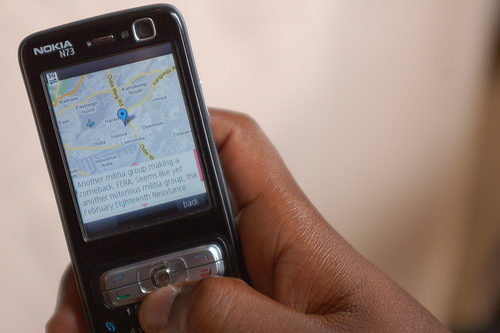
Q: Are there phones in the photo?
A: Yes, there is a phone.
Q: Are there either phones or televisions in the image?
A: Yes, there is a phone.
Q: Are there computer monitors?
A: No, there are no computer monitors.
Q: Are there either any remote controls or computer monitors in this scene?
A: No, there are no computer monitors or remote controls.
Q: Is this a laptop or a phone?
A: This is a phone.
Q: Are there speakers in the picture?
A: Yes, there is a speaker.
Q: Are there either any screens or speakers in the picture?
A: Yes, there is a speaker.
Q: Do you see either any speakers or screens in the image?
A: Yes, there is a speaker.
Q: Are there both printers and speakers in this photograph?
A: No, there is a speaker but no printers.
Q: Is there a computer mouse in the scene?
A: No, there are no computer mice.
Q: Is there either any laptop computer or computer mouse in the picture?
A: No, there are no computer mice or laptops.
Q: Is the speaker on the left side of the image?
A: Yes, the speaker is on the left of the image.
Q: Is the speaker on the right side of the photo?
A: No, the speaker is on the left of the image.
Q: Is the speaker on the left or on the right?
A: The speaker is on the left of the image.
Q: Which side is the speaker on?
A: The speaker is on the left of the image.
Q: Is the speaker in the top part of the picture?
A: Yes, the speaker is in the top of the image.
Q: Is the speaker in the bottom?
A: No, the speaker is in the top of the image.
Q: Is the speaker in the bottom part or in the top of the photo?
A: The speaker is in the top of the image.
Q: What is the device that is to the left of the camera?
A: The device is a speaker.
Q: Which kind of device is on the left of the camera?
A: The device is a speaker.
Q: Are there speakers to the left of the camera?
A: Yes, there is a speaker to the left of the camera.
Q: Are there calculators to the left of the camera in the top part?
A: No, there is a speaker to the left of the camera.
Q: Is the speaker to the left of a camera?
A: Yes, the speaker is to the left of a camera.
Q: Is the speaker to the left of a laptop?
A: No, the speaker is to the left of a camera.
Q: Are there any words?
A: Yes, there are words.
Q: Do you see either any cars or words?
A: Yes, there are words.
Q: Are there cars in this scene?
A: No, there are no cars.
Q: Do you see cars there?
A: No, there are no cars.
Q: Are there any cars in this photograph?
A: No, there are no cars.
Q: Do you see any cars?
A: No, there are no cars.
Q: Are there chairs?
A: No, there are no chairs.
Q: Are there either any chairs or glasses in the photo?
A: No, there are no chairs or glasses.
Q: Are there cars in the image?
A: No, there are no cars.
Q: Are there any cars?
A: No, there are no cars.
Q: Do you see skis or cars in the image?
A: No, there are no cars or skis.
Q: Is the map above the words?
A: Yes, the map is above the words.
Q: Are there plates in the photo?
A: No, there are no plates.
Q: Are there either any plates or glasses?
A: No, there are no plates or glasses.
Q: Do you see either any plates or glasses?
A: No, there are no plates or glasses.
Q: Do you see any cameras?
A: Yes, there is a camera.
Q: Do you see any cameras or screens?
A: Yes, there is a camera.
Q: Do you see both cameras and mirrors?
A: No, there is a camera but no mirrors.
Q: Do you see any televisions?
A: No, there are no televisions.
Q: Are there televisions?
A: No, there are no televisions.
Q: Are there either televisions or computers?
A: No, there are no televisions or computers.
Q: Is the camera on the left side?
A: Yes, the camera is on the left of the image.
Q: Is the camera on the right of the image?
A: No, the camera is on the left of the image.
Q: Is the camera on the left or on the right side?
A: The camera is on the left of the image.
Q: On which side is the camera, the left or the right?
A: The camera is on the left of the image.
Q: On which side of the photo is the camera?
A: The camera is on the left of the image.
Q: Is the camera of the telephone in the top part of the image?
A: Yes, the camera is in the top of the image.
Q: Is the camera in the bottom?
A: No, the camera is in the top of the image.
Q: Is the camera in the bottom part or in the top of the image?
A: The camera is in the top of the image.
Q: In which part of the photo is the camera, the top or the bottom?
A: The camera is in the top of the image.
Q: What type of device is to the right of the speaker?
A: The device is a camera.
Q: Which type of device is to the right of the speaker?
A: The device is a camera.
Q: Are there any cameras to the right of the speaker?
A: Yes, there is a camera to the right of the speaker.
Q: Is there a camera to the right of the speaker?
A: Yes, there is a camera to the right of the speaker.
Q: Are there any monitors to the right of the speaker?
A: No, there is a camera to the right of the speaker.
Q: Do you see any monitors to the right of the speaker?
A: No, there is a camera to the right of the speaker.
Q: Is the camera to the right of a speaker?
A: Yes, the camera is to the right of a speaker.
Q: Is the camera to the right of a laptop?
A: No, the camera is to the right of a speaker.